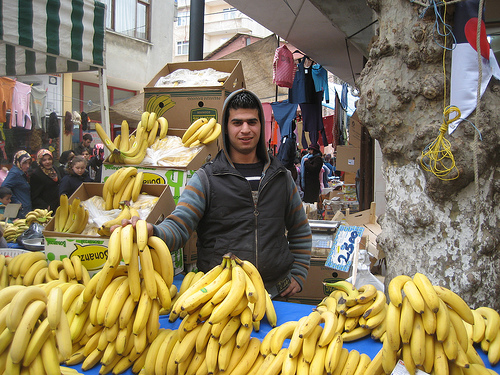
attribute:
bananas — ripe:
[99, 163, 145, 206]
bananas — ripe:
[179, 114, 223, 149]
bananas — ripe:
[89, 114, 150, 164]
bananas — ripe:
[0, 204, 56, 242]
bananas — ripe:
[48, 191, 91, 233]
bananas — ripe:
[91, 118, 149, 169]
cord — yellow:
[417, 0, 466, 182]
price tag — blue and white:
[328, 216, 365, 272]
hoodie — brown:
[216, 85, 267, 165]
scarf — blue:
[298, 148, 316, 193]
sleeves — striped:
[153, 164, 210, 251]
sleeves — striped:
[283, 164, 313, 286]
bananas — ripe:
[0, 215, 499, 373]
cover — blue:
[59, 295, 499, 373]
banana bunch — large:
[4, 216, 495, 373]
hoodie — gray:
[152, 87, 313, 294]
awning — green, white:
[2, 0, 109, 80]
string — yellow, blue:
[411, 0, 464, 186]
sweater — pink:
[269, 41, 299, 90]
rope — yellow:
[413, 0, 474, 188]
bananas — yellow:
[102, 222, 150, 272]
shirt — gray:
[151, 150, 320, 287]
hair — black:
[229, 92, 264, 112]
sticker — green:
[200, 284, 212, 296]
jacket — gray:
[156, 88, 312, 297]